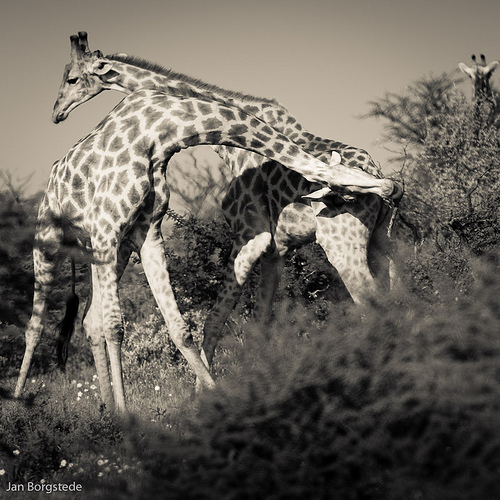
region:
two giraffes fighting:
[15, 15, 435, 422]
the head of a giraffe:
[31, 23, 125, 130]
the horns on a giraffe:
[65, 22, 96, 59]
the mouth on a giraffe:
[46, 108, 70, 125]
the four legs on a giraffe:
[6, 217, 238, 462]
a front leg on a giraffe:
[134, 242, 234, 407]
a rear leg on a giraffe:
[8, 245, 65, 402]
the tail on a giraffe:
[57, 259, 85, 382]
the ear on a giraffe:
[88, 53, 116, 80]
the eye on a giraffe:
[63, 75, 79, 85]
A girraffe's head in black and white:
[45, 22, 108, 122]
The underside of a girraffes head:
[295, 136, 410, 229]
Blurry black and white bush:
[273, 347, 483, 477]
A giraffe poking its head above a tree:
[448, 45, 498, 146]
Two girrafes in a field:
[32, 31, 405, 412]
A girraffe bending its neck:
[25, 91, 402, 385]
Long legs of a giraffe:
[5, 233, 240, 431]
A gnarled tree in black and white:
[392, 120, 499, 272]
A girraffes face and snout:
[38, 66, 95, 125]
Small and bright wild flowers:
[30, 376, 97, 486]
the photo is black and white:
[1, 3, 489, 485]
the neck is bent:
[48, 110, 415, 270]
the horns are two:
[60, 27, 120, 64]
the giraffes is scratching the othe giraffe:
[206, 105, 431, 285]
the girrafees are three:
[31, 31, 496, 402]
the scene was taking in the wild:
[5, 32, 496, 492]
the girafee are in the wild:
[25, 32, 472, 489]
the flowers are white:
[66, 375, 106, 415]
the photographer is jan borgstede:
[1, 473, 76, 498]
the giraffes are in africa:
[35, 40, 478, 440]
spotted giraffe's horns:
[57, 23, 102, 58]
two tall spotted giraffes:
[5, 20, 392, 430]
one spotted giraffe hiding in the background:
[447, 46, 494, 101]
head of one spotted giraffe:
[290, 140, 405, 220]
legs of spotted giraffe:
[15, 235, 215, 411]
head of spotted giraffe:
[31, 27, 113, 127]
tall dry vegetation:
[358, 71, 477, 148]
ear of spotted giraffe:
[86, 55, 118, 80]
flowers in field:
[8, 440, 139, 486]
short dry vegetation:
[212, 309, 497, 499]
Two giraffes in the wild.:
[30, 34, 435, 481]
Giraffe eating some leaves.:
[235, 128, 445, 222]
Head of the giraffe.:
[42, 16, 133, 141]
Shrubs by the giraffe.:
[115, 349, 301, 470]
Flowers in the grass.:
[32, 368, 146, 485]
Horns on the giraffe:
[68, 18, 156, 67]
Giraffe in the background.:
[340, 18, 496, 109]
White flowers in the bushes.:
[41, 416, 125, 478]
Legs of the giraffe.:
[27, 228, 239, 420]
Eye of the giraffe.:
[62, 50, 84, 98]